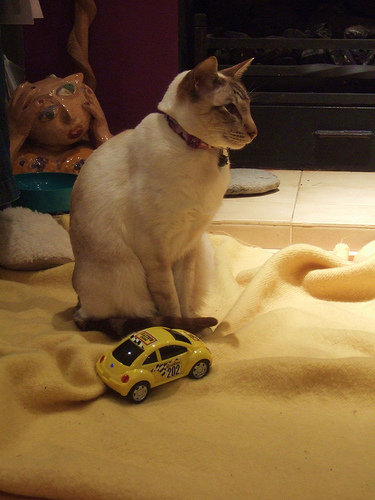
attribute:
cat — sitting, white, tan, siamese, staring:
[67, 54, 258, 335]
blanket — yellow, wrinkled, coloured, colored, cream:
[1, 237, 372, 498]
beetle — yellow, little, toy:
[95, 323, 212, 407]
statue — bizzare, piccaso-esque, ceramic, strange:
[8, 73, 114, 181]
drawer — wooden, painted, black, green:
[222, 101, 374, 172]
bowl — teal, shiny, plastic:
[7, 170, 86, 216]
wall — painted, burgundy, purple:
[21, 1, 183, 139]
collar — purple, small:
[157, 102, 229, 166]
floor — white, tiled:
[209, 160, 374, 222]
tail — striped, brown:
[76, 314, 218, 341]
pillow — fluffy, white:
[1, 205, 74, 274]